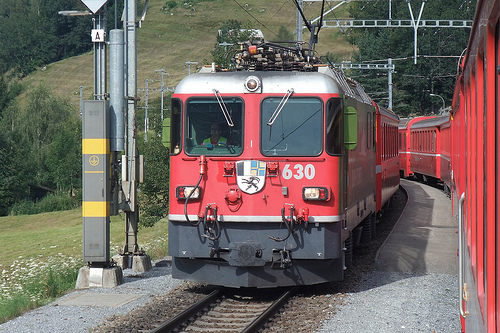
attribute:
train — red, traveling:
[172, 71, 410, 292]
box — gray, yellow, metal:
[81, 102, 109, 263]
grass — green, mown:
[4, 202, 169, 313]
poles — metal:
[84, 2, 153, 275]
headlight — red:
[181, 187, 199, 199]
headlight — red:
[299, 188, 327, 200]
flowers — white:
[4, 230, 163, 300]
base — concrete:
[115, 253, 148, 277]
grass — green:
[20, 2, 334, 96]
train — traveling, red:
[405, 0, 500, 331]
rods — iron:
[293, 7, 470, 84]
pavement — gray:
[343, 173, 465, 332]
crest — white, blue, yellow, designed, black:
[231, 157, 266, 193]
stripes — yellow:
[82, 137, 106, 225]